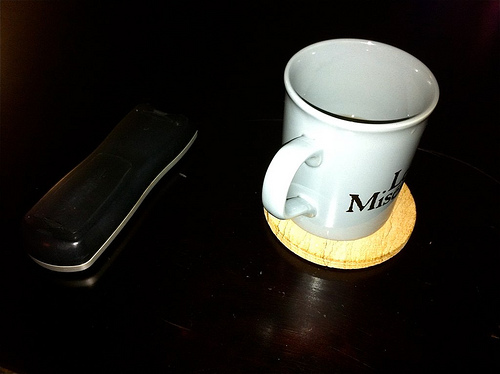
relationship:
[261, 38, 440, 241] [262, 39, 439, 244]
coffee cup on desk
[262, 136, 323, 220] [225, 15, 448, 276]
handle on cup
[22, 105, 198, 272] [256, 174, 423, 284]
remote next to a coaster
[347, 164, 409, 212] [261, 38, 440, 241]
black lettering on coffee cup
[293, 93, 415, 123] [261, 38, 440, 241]
shadow on coffee cup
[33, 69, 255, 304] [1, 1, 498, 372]
case laying on table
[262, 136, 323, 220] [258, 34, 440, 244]
handle on coffee cup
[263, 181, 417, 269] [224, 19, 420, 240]
coast under cup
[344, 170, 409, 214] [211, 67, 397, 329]
writing on cup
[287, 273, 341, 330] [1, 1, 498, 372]
light reflecting on table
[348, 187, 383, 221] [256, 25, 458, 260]
m on side cup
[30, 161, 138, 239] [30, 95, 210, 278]
batter plate on remote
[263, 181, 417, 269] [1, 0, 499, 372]
coast on coffee table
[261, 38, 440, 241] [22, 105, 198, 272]
coffee cup next to remote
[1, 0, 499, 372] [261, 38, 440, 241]
coffee table with coffee cup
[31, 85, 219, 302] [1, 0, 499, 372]
phone on coffee table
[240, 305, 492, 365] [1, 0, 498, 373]
wood on desk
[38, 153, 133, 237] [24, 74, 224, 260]
battery compartment on phone.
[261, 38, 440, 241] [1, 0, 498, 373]
coffee cup reflection on desk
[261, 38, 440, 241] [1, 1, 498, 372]
coffee cup on table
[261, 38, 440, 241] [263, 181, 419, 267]
coffee cup on coast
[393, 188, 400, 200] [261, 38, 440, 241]
writing on coffee cup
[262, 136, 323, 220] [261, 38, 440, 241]
handle of coffee cup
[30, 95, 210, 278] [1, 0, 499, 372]
remote on coffee table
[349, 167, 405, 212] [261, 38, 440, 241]
lettering on coffee cup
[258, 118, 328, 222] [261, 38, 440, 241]
handle on coffee cup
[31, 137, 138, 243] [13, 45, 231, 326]
battery cap on remote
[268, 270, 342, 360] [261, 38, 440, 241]
reflection of coffee cup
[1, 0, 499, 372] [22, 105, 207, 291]
coffee table has on it a remote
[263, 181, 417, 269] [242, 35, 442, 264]
coast under cup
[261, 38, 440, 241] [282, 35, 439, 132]
coffee cup has rim